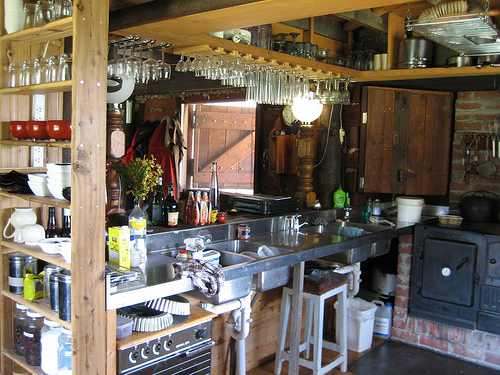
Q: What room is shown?
A: It is a kitchen.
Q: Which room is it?
A: It is a kitchen.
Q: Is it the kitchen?
A: Yes, it is the kitchen.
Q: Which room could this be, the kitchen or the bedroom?
A: It is the kitchen.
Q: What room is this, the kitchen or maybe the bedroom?
A: It is the kitchen.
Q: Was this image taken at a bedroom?
A: No, the picture was taken in a kitchen.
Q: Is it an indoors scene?
A: Yes, it is indoors.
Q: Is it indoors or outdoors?
A: It is indoors.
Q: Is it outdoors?
A: No, it is indoors.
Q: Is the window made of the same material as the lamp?
A: Yes, both the window and the lamp are made of wood.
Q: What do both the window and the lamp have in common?
A: The material, both the window and the lamp are wooden.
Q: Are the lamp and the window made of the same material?
A: Yes, both the lamp and the window are made of wood.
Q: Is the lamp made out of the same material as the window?
A: Yes, both the lamp and the window are made of wood.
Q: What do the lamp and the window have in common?
A: The material, both the lamp and the window are wooden.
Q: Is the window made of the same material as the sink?
A: No, the window is made of wood and the sink is made of metal.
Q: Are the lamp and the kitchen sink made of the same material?
A: No, the lamp is made of wood and the sink is made of metal.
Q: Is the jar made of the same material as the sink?
A: No, the jar is made of glass and the sink is made of metal.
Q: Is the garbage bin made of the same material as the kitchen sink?
A: No, the garbage bin is made of plastic and the sink is made of metal.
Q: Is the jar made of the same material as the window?
A: No, the jar is made of glass and the window is made of wood.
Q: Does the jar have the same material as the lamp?
A: No, the jar is made of glass and the lamp is made of wood.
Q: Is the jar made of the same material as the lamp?
A: No, the jar is made of glass and the lamp is made of wood.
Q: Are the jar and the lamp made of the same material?
A: No, the jar is made of glass and the lamp is made of wood.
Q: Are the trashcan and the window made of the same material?
A: No, the trashcan is made of plastic and the window is made of wood.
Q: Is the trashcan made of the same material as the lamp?
A: No, the trashcan is made of plastic and the lamp is made of wood.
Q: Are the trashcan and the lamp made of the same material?
A: No, the trashcan is made of plastic and the lamp is made of wood.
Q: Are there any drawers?
A: No, there are no drawers.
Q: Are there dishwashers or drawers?
A: No, there are no drawers or dishwashers.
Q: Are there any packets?
A: No, there are no packets.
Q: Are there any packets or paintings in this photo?
A: No, there are no packets or paintings.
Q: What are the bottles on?
A: The bottles are on the counter.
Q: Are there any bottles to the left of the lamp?
A: Yes, there are bottles to the left of the lamp.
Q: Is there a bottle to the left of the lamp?
A: Yes, there are bottles to the left of the lamp.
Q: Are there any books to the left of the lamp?
A: No, there are bottles to the left of the lamp.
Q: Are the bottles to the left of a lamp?
A: Yes, the bottles are to the left of a lamp.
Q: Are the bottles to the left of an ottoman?
A: No, the bottles are to the left of a lamp.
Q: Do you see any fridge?
A: No, there are no refrigerators.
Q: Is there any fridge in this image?
A: No, there are no refrigerators.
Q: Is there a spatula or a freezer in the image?
A: No, there are no refrigerators or spatulas.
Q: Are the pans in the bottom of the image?
A: Yes, the pans are in the bottom of the image.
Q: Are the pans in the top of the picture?
A: No, the pans are in the bottom of the image.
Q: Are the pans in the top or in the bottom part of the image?
A: The pans are in the bottom of the image.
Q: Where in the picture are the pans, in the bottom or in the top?
A: The pans are in the bottom of the image.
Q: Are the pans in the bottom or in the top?
A: The pans are in the bottom of the image.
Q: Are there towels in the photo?
A: Yes, there is a towel.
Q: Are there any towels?
A: Yes, there is a towel.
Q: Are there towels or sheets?
A: Yes, there is a towel.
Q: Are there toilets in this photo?
A: No, there are no toilets.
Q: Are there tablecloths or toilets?
A: No, there are no toilets or tablecloths.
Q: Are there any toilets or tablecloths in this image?
A: No, there are no toilets or tablecloths.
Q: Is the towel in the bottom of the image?
A: Yes, the towel is in the bottom of the image.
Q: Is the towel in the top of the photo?
A: No, the towel is in the bottom of the image.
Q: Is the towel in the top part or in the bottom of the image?
A: The towel is in the bottom of the image.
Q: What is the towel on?
A: The towel is on the counter.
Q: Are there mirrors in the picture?
A: No, there are no mirrors.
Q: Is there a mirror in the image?
A: No, there are no mirrors.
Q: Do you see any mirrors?
A: No, there are no mirrors.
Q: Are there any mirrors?
A: No, there are no mirrors.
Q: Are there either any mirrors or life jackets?
A: No, there are no mirrors or life jackets.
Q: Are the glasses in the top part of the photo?
A: Yes, the glasses are in the top of the image.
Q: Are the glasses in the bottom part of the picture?
A: No, the glasses are in the top of the image.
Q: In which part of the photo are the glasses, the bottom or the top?
A: The glasses are in the top of the image.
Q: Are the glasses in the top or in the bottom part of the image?
A: The glasses are in the top of the image.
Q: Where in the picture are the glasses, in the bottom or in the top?
A: The glasses are in the top of the image.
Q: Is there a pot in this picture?
A: Yes, there is a pot.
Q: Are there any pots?
A: Yes, there is a pot.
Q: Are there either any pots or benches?
A: Yes, there is a pot.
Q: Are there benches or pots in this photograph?
A: Yes, there is a pot.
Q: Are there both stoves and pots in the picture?
A: Yes, there are both a pot and a stove.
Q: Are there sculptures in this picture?
A: No, there are no sculptures.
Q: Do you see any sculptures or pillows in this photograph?
A: No, there are no sculptures or pillows.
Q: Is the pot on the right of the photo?
A: Yes, the pot is on the right of the image.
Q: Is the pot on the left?
A: No, the pot is on the right of the image.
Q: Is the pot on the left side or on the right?
A: The pot is on the right of the image.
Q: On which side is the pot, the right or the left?
A: The pot is on the right of the image.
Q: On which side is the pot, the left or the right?
A: The pot is on the right of the image.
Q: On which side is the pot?
A: The pot is on the right of the image.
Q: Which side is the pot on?
A: The pot is on the right of the image.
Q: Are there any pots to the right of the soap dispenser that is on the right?
A: Yes, there is a pot to the right of the soap dispenser.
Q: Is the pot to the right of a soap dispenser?
A: Yes, the pot is to the right of a soap dispenser.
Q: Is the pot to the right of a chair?
A: No, the pot is to the right of a soap dispenser.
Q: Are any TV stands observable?
A: No, there are no TV stands.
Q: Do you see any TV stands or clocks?
A: No, there are no TV stands or clocks.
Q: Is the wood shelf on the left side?
A: Yes, the shelf is on the left of the image.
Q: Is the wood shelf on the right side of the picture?
A: No, the shelf is on the left of the image.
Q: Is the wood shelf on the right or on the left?
A: The shelf is on the left of the image.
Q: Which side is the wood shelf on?
A: The shelf is on the left of the image.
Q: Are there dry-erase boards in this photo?
A: No, there are no dry-erase boards.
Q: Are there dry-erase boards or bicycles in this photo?
A: No, there are no dry-erase boards or bicycles.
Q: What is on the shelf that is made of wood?
A: The dishes are on the shelf.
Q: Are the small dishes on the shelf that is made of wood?
A: Yes, the dishes are on the shelf.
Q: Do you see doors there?
A: Yes, there is a door.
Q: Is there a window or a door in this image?
A: Yes, there is a door.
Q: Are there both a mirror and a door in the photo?
A: No, there is a door but no mirrors.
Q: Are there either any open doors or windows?
A: Yes, there is an open door.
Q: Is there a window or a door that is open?
A: Yes, the door is open.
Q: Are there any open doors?
A: Yes, there is an open door.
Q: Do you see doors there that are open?
A: Yes, there is a door that is open.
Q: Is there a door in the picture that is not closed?
A: Yes, there is a open door.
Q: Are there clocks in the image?
A: No, there are no clocks.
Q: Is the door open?
A: Yes, the door is open.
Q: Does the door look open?
A: Yes, the door is open.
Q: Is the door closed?
A: No, the door is open.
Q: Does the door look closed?
A: No, the door is open.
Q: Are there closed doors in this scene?
A: No, there is a door but it is open.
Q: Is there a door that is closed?
A: No, there is a door but it is open.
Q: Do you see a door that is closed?
A: No, there is a door but it is open.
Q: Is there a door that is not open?
A: No, there is a door but it is open.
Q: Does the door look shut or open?
A: The door is open.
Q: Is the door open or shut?
A: The door is open.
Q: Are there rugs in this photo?
A: No, there are no rugs.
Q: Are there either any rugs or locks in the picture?
A: No, there are no rugs or locks.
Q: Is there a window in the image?
A: Yes, there is a window.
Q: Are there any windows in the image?
A: Yes, there is a window.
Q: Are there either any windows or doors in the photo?
A: Yes, there is a window.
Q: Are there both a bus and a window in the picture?
A: No, there is a window but no buses.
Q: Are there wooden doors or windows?
A: Yes, there is a wood window.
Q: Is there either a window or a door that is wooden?
A: Yes, the window is wooden.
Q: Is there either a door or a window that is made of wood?
A: Yes, the window is made of wood.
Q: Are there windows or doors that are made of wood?
A: Yes, the window is made of wood.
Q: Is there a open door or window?
A: Yes, there is an open window.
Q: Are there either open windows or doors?
A: Yes, there is an open window.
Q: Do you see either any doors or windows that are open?
A: Yes, the window is open.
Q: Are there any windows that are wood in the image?
A: Yes, there is a wood window.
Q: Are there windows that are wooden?
A: Yes, there is a window that is wooden.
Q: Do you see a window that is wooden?
A: Yes, there is a window that is wooden.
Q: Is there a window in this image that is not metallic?
A: Yes, there is a wooden window.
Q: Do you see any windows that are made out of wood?
A: Yes, there is a window that is made of wood.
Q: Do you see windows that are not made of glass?
A: Yes, there is a window that is made of wood.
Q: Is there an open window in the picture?
A: Yes, there is an open window.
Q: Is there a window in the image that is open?
A: Yes, there is a window that is open.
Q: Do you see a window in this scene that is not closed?
A: Yes, there is a open window.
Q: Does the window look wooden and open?
A: Yes, the window is wooden and open.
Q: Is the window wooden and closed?
A: No, the window is wooden but open.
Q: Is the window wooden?
A: Yes, the window is wooden.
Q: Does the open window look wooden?
A: Yes, the window is wooden.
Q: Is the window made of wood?
A: Yes, the window is made of wood.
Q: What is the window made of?
A: The window is made of wood.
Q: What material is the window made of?
A: The window is made of wood.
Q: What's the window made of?
A: The window is made of wood.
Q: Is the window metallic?
A: No, the window is wooden.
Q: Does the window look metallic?
A: No, the window is wooden.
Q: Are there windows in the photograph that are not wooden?
A: No, there is a window but it is wooden.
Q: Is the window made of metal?
A: No, the window is made of wood.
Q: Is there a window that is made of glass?
A: No, there is a window but it is made of wood.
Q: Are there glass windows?
A: No, there is a window but it is made of wood.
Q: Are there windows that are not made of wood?
A: No, there is a window but it is made of wood.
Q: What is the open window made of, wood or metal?
A: The window is made of wood.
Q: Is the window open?
A: Yes, the window is open.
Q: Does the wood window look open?
A: Yes, the window is open.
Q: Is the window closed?
A: No, the window is open.